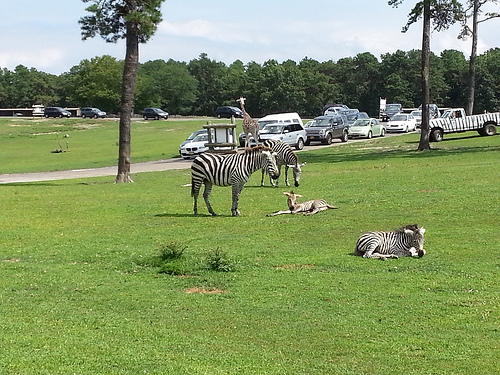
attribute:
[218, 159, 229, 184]
stripe — black 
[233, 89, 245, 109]
head — twisted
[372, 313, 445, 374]
lawn — green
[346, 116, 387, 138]
car — parked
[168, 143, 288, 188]
zebra — black 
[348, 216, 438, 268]
zebra — striped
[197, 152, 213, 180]
stripe — black 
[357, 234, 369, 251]
stripe — black 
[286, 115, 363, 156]
car — parked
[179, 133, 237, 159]
car — parked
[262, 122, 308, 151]
car — parked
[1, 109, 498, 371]
zoo — outdoor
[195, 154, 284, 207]
zebra — in grass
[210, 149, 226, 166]
stripe — black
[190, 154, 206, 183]
stripe — black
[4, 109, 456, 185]
street — narrow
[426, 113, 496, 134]
stripes — zebra